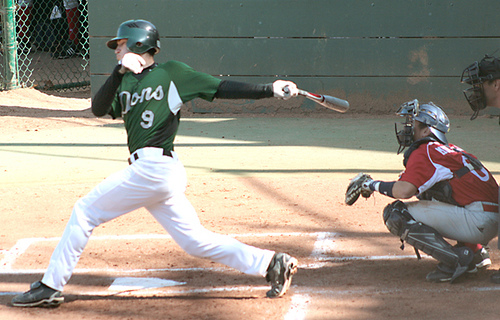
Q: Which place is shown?
A: It is a field.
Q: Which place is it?
A: It is a field.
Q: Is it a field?
A: Yes, it is a field.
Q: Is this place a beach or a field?
A: It is a field.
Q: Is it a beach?
A: No, it is a field.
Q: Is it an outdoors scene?
A: Yes, it is outdoors.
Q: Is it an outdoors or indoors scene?
A: It is outdoors.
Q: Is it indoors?
A: No, it is outdoors.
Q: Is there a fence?
A: Yes, there is a fence.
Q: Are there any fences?
A: Yes, there is a fence.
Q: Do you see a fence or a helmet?
A: Yes, there is a fence.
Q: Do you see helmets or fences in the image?
A: Yes, there is a fence.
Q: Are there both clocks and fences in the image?
A: No, there is a fence but no clocks.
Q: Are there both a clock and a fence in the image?
A: No, there is a fence but no clocks.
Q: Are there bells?
A: No, there are no bells.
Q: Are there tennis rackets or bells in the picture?
A: No, there are no bells or tennis rackets.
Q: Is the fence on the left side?
A: Yes, the fence is on the left of the image.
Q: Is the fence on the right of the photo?
A: No, the fence is on the left of the image.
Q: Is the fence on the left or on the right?
A: The fence is on the left of the image.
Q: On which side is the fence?
A: The fence is on the left of the image.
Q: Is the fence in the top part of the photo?
A: Yes, the fence is in the top of the image.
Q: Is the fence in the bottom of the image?
A: No, the fence is in the top of the image.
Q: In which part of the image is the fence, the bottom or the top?
A: The fence is in the top of the image.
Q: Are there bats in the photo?
A: Yes, there is a bat.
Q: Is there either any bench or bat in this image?
A: Yes, there is a bat.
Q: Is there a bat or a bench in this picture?
A: Yes, there is a bat.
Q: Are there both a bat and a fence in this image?
A: Yes, there are both a bat and a fence.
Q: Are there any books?
A: No, there are no books.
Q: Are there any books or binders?
A: No, there are no books or binders.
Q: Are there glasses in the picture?
A: No, there are no glasses.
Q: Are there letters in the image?
A: Yes, there are letters.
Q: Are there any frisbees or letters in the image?
A: Yes, there are letters.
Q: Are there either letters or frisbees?
A: Yes, there are letters.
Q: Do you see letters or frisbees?
A: Yes, there are letters.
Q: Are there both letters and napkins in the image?
A: No, there are letters but no napkins.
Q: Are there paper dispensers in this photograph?
A: No, there are no paper dispensers.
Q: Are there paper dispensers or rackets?
A: No, there are no paper dispensers or rackets.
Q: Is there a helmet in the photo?
A: Yes, there is a helmet.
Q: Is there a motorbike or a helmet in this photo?
A: Yes, there is a helmet.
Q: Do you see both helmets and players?
A: Yes, there are both a helmet and a player.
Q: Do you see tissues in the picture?
A: No, there are no tissues.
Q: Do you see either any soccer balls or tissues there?
A: No, there are no tissues or soccer balls.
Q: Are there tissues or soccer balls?
A: No, there are no tissues or soccer balls.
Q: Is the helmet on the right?
A: Yes, the helmet is on the right of the image.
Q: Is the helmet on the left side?
A: No, the helmet is on the right of the image.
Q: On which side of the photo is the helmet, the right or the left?
A: The helmet is on the right of the image.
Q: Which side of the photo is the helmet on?
A: The helmet is on the right of the image.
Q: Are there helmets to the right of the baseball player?
A: Yes, there is a helmet to the right of the player.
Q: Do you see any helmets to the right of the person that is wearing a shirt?
A: Yes, there is a helmet to the right of the player.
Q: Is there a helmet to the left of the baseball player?
A: No, the helmet is to the right of the player.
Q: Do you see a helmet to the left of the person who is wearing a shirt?
A: No, the helmet is to the right of the player.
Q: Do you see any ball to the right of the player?
A: No, there is a helmet to the right of the player.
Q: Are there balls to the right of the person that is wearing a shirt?
A: No, there is a helmet to the right of the player.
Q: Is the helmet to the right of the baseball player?
A: Yes, the helmet is to the right of the player.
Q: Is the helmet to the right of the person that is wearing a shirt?
A: Yes, the helmet is to the right of the player.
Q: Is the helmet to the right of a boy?
A: No, the helmet is to the right of the player.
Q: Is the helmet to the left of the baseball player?
A: No, the helmet is to the right of the player.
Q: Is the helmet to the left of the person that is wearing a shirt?
A: No, the helmet is to the right of the player.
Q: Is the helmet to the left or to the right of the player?
A: The helmet is to the right of the player.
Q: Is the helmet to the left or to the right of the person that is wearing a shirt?
A: The helmet is to the right of the player.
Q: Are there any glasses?
A: No, there are no glasses.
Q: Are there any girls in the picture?
A: No, there are no girls.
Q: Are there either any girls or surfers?
A: No, there are no girls or surfers.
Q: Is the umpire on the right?
A: Yes, the umpire is on the right of the image.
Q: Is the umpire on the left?
A: No, the umpire is on the right of the image.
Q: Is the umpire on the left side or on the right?
A: The umpire is on the right of the image.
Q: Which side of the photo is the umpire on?
A: The umpire is on the right of the image.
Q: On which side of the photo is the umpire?
A: The umpire is on the right of the image.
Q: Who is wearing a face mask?
A: The umpire is wearing a face mask.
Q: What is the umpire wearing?
A: The umpire is wearing a face mask.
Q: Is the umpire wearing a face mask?
A: Yes, the umpire is wearing a face mask.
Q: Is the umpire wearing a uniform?
A: No, the umpire is wearing a face mask.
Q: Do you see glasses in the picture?
A: No, there are no glasses.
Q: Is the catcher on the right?
A: Yes, the catcher is on the right of the image.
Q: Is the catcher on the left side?
A: No, the catcher is on the right of the image.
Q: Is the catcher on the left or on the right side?
A: The catcher is on the right of the image.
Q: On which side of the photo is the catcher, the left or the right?
A: The catcher is on the right of the image.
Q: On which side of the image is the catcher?
A: The catcher is on the right of the image.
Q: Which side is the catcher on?
A: The catcher is on the right of the image.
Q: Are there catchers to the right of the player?
A: Yes, there is a catcher to the right of the player.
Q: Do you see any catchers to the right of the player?
A: Yes, there is a catcher to the right of the player.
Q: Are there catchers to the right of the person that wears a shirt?
A: Yes, there is a catcher to the right of the player.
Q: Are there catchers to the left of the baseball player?
A: No, the catcher is to the right of the player.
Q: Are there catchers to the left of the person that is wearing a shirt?
A: No, the catcher is to the right of the player.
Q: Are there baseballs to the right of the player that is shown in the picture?
A: No, there is a catcher to the right of the player.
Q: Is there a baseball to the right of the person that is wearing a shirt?
A: No, there is a catcher to the right of the player.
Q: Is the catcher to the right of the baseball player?
A: Yes, the catcher is to the right of the player.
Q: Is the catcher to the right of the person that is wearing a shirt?
A: Yes, the catcher is to the right of the player.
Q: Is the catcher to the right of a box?
A: No, the catcher is to the right of the player.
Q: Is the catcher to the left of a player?
A: No, the catcher is to the right of a player.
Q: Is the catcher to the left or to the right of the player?
A: The catcher is to the right of the player.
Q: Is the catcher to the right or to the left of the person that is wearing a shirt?
A: The catcher is to the right of the player.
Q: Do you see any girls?
A: No, there are no girls.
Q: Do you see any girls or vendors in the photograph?
A: No, there are no girls or vendors.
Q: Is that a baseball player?
A: Yes, that is a baseball player.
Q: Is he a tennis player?
A: No, that is a baseball player.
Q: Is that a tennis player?
A: No, that is a baseball player.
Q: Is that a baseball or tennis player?
A: That is a baseball player.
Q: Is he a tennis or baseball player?
A: That is a baseball player.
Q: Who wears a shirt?
A: The player wears a shirt.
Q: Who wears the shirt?
A: The player wears a shirt.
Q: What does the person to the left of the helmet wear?
A: The player wears a shirt.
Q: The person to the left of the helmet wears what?
A: The player wears a shirt.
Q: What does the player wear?
A: The player wears a shirt.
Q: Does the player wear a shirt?
A: Yes, the player wears a shirt.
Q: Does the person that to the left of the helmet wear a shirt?
A: Yes, the player wears a shirt.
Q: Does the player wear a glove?
A: No, the player wears a shirt.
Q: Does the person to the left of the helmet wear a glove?
A: No, the player wears a shirt.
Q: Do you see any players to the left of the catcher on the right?
A: Yes, there is a player to the left of the catcher.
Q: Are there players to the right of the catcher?
A: No, the player is to the left of the catcher.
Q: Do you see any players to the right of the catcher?
A: No, the player is to the left of the catcher.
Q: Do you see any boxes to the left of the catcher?
A: No, there is a player to the left of the catcher.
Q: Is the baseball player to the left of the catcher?
A: Yes, the player is to the left of the catcher.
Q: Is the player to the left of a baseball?
A: No, the player is to the left of the catcher.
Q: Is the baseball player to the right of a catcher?
A: No, the player is to the left of a catcher.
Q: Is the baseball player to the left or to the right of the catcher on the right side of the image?
A: The player is to the left of the catcher.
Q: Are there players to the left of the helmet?
A: Yes, there is a player to the left of the helmet.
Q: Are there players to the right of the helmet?
A: No, the player is to the left of the helmet.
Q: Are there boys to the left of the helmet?
A: No, there is a player to the left of the helmet.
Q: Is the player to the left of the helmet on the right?
A: Yes, the player is to the left of the helmet.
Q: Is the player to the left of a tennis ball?
A: No, the player is to the left of the helmet.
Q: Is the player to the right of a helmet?
A: No, the player is to the left of a helmet.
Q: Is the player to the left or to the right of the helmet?
A: The player is to the left of the helmet.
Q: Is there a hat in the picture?
A: Yes, there is a hat.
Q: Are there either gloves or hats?
A: Yes, there is a hat.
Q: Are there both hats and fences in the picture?
A: Yes, there are both a hat and a fence.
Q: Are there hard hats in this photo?
A: Yes, there is a hard hat.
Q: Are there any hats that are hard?
A: Yes, there is a hat that is hard.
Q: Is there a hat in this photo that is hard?
A: Yes, there is a hat that is hard.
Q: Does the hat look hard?
A: Yes, the hat is hard.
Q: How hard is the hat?
A: The hat is hard.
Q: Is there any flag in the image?
A: No, there are no flags.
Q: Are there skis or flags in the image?
A: No, there are no flags or skis.